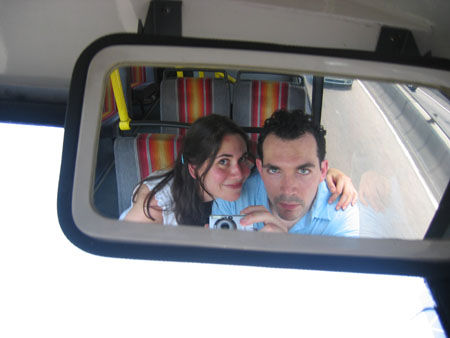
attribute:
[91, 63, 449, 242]
mirror — reflective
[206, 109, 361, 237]
man — sitting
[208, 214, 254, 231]
camera — silver, black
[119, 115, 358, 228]
woman — sitting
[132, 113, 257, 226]
hair — long, brown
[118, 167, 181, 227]
top — sleeveless, white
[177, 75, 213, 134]
stripes — multi-colored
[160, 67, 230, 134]
seat — grey,red, yellow, multi-colored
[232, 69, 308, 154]
seat — grey,red, yellow, multi-colored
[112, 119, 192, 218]
seat — grey,red, yellow, multi-colored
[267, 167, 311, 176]
eyes — blue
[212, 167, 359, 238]
shirt — light sky blue, short sleeved, blue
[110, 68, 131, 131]
pole — yellow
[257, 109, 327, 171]
hair — receding, short, curly, black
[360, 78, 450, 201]
divider — concrete